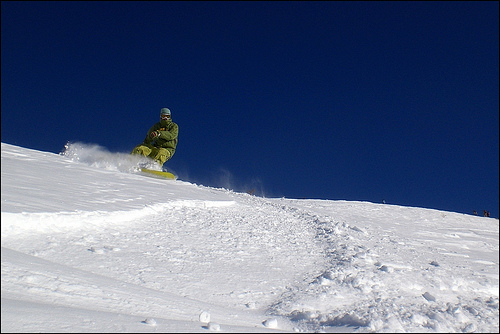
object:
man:
[129, 107, 181, 171]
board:
[144, 168, 185, 184]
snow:
[366, 249, 416, 282]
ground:
[0, 182, 499, 332]